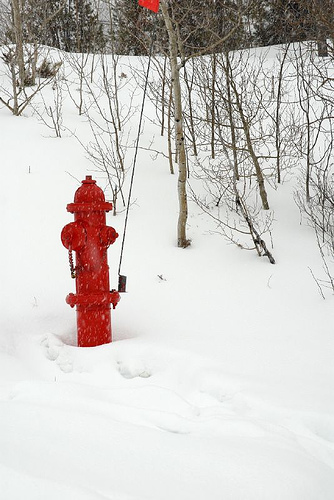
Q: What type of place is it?
A: It is a field.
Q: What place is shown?
A: It is a field.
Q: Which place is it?
A: It is a field.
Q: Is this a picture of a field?
A: Yes, it is showing a field.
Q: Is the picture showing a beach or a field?
A: It is showing a field.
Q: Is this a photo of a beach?
A: No, the picture is showing a field.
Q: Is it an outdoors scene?
A: Yes, it is outdoors.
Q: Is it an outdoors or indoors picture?
A: It is outdoors.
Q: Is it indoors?
A: No, it is outdoors.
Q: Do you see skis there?
A: No, there are no skis.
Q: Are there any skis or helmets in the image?
A: No, there are no skis or helmets.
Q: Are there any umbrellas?
A: No, there are no umbrellas.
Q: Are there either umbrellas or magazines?
A: No, there are no umbrellas or magazines.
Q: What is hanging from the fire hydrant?
A: The chain is hanging from the fire hydrant.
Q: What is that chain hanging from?
A: The chain is hanging from the hydrant.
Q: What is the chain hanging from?
A: The chain is hanging from the hydrant.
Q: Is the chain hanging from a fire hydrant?
A: Yes, the chain is hanging from a fire hydrant.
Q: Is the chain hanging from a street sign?
A: No, the chain is hanging from a fire hydrant.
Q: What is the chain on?
A: The chain is on the hydrant.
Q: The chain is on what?
A: The chain is on the hydrant.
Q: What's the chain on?
A: The chain is on the hydrant.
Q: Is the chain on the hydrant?
A: Yes, the chain is on the hydrant.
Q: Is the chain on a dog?
A: No, the chain is on the hydrant.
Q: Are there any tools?
A: No, there are no tools.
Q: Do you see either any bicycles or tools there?
A: No, there are no tools or bicycles.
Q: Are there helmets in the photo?
A: No, there are no helmets.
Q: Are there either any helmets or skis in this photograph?
A: No, there are no helmets or skis.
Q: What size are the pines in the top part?
A: The pines are large.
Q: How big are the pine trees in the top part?
A: The pine trees are large.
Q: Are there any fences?
A: No, there are no fences.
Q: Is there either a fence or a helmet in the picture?
A: No, there are no fences or helmets.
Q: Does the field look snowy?
A: Yes, the field is snowy.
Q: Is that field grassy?
A: No, the field is snowy.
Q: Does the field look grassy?
A: No, the field is snowy.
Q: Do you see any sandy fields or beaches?
A: No, there is a field but it is snowy.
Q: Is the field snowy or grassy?
A: The field is snowy.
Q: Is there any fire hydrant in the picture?
A: Yes, there is a fire hydrant.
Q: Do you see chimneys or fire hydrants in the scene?
A: Yes, there is a fire hydrant.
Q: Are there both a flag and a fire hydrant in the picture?
A: Yes, there are both a fire hydrant and a flag.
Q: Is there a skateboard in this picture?
A: No, there are no skateboards.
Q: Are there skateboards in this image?
A: No, there are no skateboards.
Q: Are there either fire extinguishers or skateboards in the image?
A: No, there are no skateboards or fire extinguishers.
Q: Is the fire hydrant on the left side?
A: Yes, the fire hydrant is on the left of the image.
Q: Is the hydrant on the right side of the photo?
A: No, the hydrant is on the left of the image.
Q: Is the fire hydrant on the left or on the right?
A: The fire hydrant is on the left of the image.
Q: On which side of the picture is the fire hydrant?
A: The fire hydrant is on the left of the image.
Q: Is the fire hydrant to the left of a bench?
A: No, the fire hydrant is to the left of the flag.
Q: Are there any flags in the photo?
A: Yes, there is a flag.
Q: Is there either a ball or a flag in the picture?
A: Yes, there is a flag.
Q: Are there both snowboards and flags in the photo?
A: No, there is a flag but no snowboards.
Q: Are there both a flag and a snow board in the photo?
A: No, there is a flag but no snowboards.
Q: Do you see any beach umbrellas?
A: No, there are no beach umbrellas.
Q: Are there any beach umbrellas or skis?
A: No, there are no beach umbrellas or skis.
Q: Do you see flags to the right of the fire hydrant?
A: Yes, there is a flag to the right of the fire hydrant.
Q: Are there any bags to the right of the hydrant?
A: No, there is a flag to the right of the hydrant.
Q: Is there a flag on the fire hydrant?
A: Yes, there is a flag on the fire hydrant.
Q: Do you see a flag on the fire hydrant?
A: Yes, there is a flag on the fire hydrant.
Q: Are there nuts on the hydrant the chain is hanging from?
A: No, there is a flag on the hydrant.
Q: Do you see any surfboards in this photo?
A: No, there are no surfboards.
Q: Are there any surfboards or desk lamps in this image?
A: No, there are no surfboards or desk lamps.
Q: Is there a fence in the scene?
A: No, there are no fences.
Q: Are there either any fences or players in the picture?
A: No, there are no fences or players.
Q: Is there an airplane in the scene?
A: No, there are no airplanes.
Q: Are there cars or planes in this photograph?
A: No, there are no planes or cars.